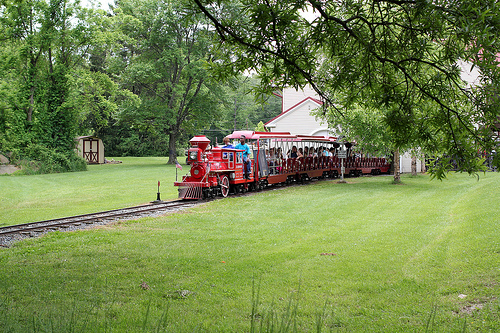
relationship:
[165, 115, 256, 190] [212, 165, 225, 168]
train little red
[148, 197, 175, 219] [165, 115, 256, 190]
tracks in front of train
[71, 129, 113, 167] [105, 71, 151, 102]
shed in distance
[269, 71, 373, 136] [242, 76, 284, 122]
building in background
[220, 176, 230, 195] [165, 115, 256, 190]
wheel on a train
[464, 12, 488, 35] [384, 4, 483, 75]
leaves on a tree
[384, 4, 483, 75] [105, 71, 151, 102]
tree in distance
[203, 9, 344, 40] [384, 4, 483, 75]
branch on a tree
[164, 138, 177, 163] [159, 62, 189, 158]
trunk of a tree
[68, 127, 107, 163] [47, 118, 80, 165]
barn in bushes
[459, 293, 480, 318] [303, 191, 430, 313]
cut freshly lawn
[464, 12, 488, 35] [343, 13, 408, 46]
leaves on branches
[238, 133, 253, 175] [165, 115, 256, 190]
conductor of train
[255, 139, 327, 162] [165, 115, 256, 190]
people riding train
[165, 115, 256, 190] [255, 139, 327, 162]
train filled with people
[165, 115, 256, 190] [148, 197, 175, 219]
train on tracks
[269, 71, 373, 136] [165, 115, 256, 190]
building behind train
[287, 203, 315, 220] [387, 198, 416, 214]
grass tall green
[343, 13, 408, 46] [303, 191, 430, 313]
branches over lawn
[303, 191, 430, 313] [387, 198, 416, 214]
lawn nice green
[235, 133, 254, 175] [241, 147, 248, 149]
conductor in shirt blue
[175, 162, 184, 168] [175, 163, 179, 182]
flag on pole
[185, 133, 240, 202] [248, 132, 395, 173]
engine pulling cars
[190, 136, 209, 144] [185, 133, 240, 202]
smoke stack on engine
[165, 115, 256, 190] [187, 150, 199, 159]
train has a head light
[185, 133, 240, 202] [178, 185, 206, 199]
engine has a cowcatcher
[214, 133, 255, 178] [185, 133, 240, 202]
engineers riding engine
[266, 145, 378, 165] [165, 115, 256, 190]
passengers riding in train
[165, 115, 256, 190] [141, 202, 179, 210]
train on a guage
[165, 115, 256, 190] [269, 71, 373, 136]
train out of building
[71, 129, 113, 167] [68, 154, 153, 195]
shed in yard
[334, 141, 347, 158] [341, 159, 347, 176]
sign on a pole